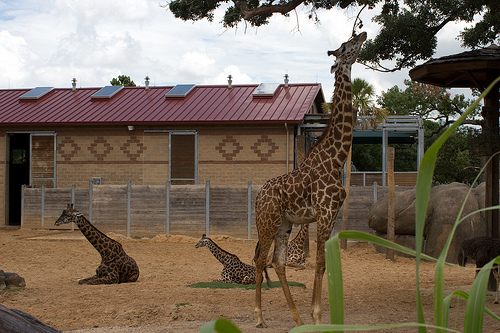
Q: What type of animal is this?
A: Giraffe.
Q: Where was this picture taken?
A: Zoo.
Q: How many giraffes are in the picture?
A: 4.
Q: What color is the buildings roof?
A: Red.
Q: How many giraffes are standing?
A: 1.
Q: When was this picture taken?
A: Daytime.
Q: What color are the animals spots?
A: Brown.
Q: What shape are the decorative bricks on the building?
A: Diamond.